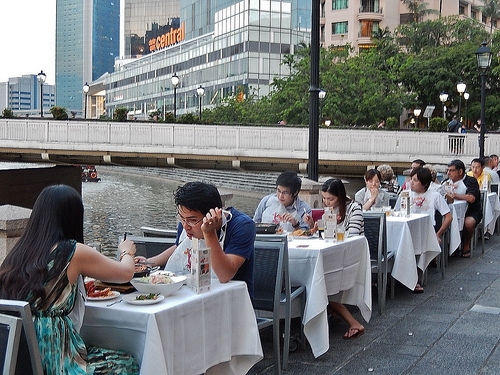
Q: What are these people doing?
A: Eating.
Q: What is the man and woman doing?
A: Talking.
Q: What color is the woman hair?
A: Long black.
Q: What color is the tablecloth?
A: White.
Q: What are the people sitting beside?
A: The river.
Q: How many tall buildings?
A: 5.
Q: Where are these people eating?
A: At an outdoor restaurant.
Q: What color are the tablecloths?
A: White.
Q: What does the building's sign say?
A: Central.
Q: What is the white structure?
A: Bridge.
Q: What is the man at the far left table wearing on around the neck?
A: Bib.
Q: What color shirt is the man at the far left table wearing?
A: Blue.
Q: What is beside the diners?
A: Water.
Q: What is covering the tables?
A: Tablecloths.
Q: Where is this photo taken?
A: On an outside patio.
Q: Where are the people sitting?
A: On a patio.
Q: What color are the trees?
A: Green.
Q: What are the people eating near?
A: Water.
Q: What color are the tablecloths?
A: White.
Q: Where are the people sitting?
A: Outside tables.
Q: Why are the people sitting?
A: They are eating.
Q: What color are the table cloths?
A: White.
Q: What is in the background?
A: City buildings.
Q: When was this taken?
A: Daytime.